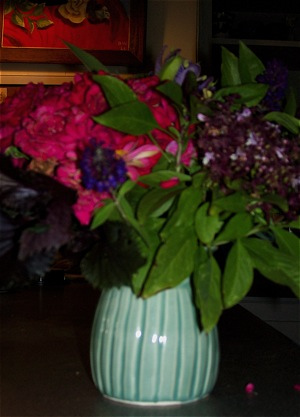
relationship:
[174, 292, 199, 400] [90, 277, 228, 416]
bands on vase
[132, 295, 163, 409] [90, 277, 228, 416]
bands on vase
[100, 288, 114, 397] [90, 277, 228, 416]
bands on vase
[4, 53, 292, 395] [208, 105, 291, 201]
arrangement has flowers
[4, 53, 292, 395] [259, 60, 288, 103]
arrangement has flowers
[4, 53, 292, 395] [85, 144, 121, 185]
arrangement has flowers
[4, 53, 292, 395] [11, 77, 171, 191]
arrangement has flowers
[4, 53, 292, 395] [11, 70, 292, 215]
arrangement has flowers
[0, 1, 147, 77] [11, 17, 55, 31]
artwork has painting leaves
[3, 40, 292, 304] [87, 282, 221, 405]
flowers are in vase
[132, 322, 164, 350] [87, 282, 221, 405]
lights on vase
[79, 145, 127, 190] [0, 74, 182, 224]
flower next to pink flowers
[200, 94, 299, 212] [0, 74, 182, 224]
purple flower next to pink flowers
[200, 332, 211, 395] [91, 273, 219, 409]
line on vase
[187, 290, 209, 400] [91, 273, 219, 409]
line on vase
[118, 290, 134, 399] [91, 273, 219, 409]
line on vase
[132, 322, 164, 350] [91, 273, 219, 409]
lights shining on vase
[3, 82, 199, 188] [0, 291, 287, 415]
flower on table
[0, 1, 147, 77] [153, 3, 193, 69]
artwork on wall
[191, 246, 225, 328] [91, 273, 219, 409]
leaf hanging over side of vase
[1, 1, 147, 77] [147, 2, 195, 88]
artwork hanging on wall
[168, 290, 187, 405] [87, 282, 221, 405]
line on vase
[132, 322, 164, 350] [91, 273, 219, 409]
lights on vase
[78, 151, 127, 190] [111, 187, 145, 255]
flower on stem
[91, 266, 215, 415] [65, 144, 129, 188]
vase of flowers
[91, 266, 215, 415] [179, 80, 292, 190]
vase of flowers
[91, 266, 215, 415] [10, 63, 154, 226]
vase of flowers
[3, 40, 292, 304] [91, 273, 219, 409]
flowers in a vase